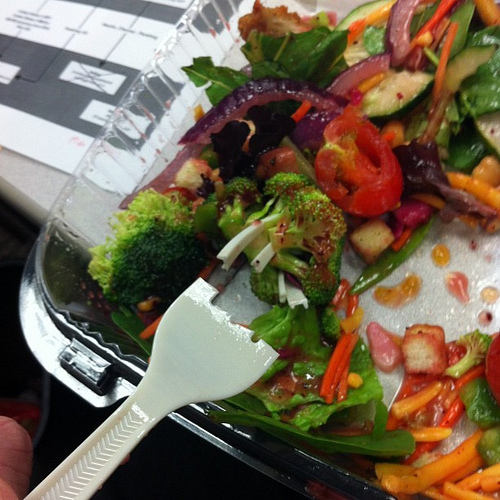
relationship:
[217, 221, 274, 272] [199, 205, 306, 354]
prong has snapped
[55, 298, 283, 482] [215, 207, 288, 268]
fork has prong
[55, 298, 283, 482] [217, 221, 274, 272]
fork has prong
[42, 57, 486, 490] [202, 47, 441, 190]
container of salad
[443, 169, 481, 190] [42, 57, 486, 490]
carrot in container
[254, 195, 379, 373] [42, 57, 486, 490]
broccoli in container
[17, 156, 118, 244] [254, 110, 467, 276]
table under food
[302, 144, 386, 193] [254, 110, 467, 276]
tomato in food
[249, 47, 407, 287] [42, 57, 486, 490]
vegetables in container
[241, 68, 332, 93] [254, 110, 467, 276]
onion in food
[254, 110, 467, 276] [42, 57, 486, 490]
food in container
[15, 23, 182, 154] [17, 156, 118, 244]
paper on table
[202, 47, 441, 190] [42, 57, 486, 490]
salad in container